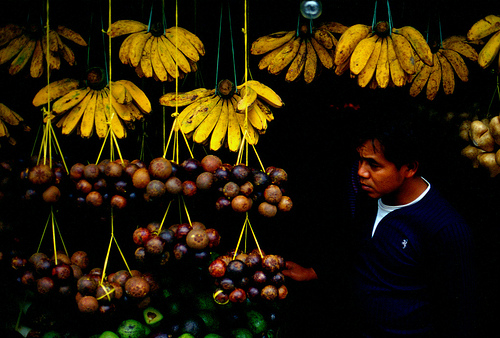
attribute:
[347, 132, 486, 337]
man — looking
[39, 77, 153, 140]
bananas — ripe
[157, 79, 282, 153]
bananas — yellow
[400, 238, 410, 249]
logo — white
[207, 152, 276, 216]
fruit — reddish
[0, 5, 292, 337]
different fruit — hanging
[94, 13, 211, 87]
bananas — ripe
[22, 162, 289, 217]
fruit — purple, hanging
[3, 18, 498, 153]
plantains — ripe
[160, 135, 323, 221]
round fruit — purplish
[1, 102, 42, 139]
bunch — yellow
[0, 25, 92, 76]
bunch — yellow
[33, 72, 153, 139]
bunch — yellow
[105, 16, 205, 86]
bunch — yellow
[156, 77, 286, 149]
bunch — yellow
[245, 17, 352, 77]
bunch — yellow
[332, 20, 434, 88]
bunch — yellow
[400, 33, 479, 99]
bunch — yellow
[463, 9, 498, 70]
bunch — yellow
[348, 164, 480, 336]
sweater — navy blue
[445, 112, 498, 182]
potatoes — bunched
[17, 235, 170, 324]
fruits — ripe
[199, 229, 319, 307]
fruit — round, reddish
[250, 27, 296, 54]
banana — ripe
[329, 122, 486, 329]
man — looking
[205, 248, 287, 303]
fruit — small, shiny, black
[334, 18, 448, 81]
bananas — ripe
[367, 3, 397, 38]
string — green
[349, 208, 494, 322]
shirt — blue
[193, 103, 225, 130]
skin — yellow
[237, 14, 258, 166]
string — yellow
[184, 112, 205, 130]
blemish — brown